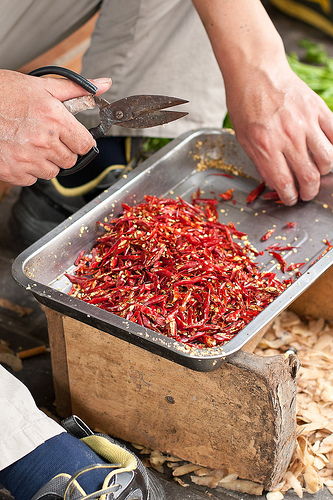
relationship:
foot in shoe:
[69, 449, 109, 489] [48, 415, 155, 499]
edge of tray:
[37, 283, 119, 338] [21, 117, 324, 356]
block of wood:
[56, 308, 310, 486] [247, 354, 289, 500]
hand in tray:
[226, 68, 331, 193] [21, 117, 324, 356]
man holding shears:
[2, 3, 332, 205] [69, 88, 187, 143]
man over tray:
[2, 3, 332, 205] [21, 117, 324, 356]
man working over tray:
[2, 3, 332, 205] [21, 117, 324, 356]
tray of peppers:
[21, 117, 324, 356] [143, 214, 242, 294]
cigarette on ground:
[14, 341, 50, 360] [32, 366, 53, 397]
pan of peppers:
[21, 117, 324, 356] [143, 214, 242, 294]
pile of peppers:
[150, 278, 212, 333] [143, 214, 242, 294]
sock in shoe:
[14, 432, 99, 493] [48, 415, 155, 499]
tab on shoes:
[63, 413, 94, 441] [48, 415, 155, 499]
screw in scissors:
[115, 110, 127, 120] [69, 88, 187, 143]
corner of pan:
[181, 117, 246, 184] [21, 117, 324, 356]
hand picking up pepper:
[226, 68, 331, 193] [251, 182, 271, 203]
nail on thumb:
[94, 77, 114, 85] [43, 71, 118, 105]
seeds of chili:
[233, 203, 272, 222] [263, 222, 273, 243]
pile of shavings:
[150, 278, 212, 333] [295, 330, 333, 480]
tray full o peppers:
[21, 117, 324, 356] [143, 214, 242, 294]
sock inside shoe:
[14, 432, 99, 493] [48, 415, 155, 499]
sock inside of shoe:
[14, 432, 99, 493] [48, 415, 155, 499]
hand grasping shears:
[226, 68, 331, 193] [69, 88, 187, 143]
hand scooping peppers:
[226, 68, 331, 193] [143, 214, 242, 294]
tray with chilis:
[21, 117, 324, 356] [71, 258, 105, 314]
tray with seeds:
[21, 117, 324, 356] [233, 203, 272, 222]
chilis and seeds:
[71, 258, 105, 314] [233, 203, 272, 222]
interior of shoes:
[94, 437, 129, 466] [48, 415, 155, 499]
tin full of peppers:
[21, 117, 324, 356] [143, 214, 242, 294]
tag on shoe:
[63, 413, 94, 441] [48, 415, 155, 499]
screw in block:
[115, 110, 127, 120] [56, 308, 310, 486]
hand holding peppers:
[226, 68, 331, 193] [143, 214, 242, 294]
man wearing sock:
[2, 3, 332, 205] [14, 432, 99, 493]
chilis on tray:
[71, 258, 105, 314] [21, 117, 324, 356]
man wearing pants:
[2, 3, 332, 205] [4, 0, 234, 135]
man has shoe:
[2, 3, 332, 205] [48, 415, 155, 499]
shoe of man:
[48, 415, 155, 499] [2, 3, 332, 205]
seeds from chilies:
[233, 203, 272, 222] [207, 242, 239, 288]